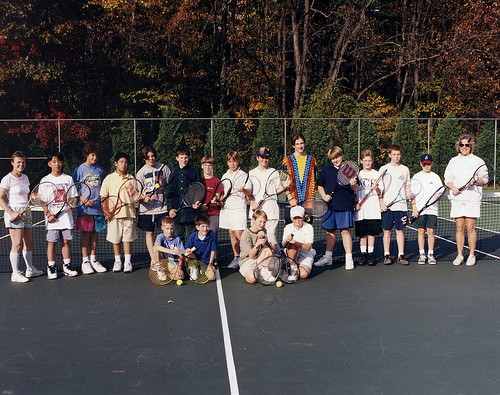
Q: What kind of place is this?
A: A tennis court.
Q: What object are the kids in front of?
A: A tennis net.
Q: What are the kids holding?
A: Rackets.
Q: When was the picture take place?
A: Daytime.